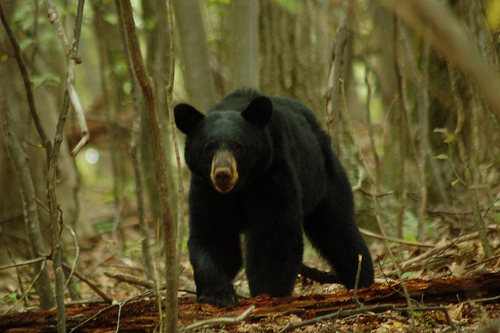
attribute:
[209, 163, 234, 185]
nose — bears, brown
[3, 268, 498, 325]
log — rotten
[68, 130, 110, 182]
camera glare — big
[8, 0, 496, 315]
trees — back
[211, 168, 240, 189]
mouth — closed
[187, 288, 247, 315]
claws — long, curves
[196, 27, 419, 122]
trees — back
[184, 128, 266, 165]
eyes — bears, black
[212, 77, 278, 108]
muscle — shoulder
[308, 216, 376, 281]
leg — bears, hind, black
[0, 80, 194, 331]
weeds — high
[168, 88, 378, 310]
bear — black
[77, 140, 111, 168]
glare — big, camera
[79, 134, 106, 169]
glare — big, camera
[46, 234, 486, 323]
twigs — brown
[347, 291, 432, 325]
leaves — crushed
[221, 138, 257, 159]
eyes — small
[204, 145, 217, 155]
eyes — small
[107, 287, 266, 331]
tree — dead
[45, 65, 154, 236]
branch — is from a tree